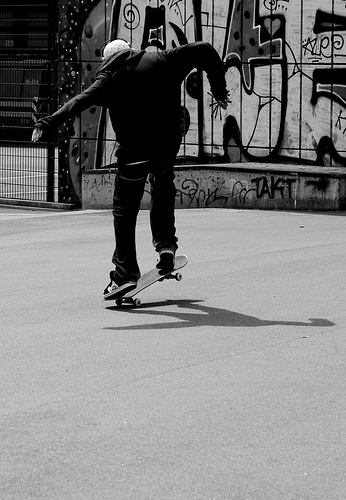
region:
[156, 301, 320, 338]
a shadow on the ground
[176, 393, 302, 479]
the ground is grey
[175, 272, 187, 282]
a wheel on the skateboard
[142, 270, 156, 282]
the skateboard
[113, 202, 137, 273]
person is wearing black pants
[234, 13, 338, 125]
tagging on the wall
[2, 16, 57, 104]
a fence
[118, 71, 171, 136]
a black sweater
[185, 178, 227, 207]
tagging on the wall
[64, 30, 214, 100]
the man is wearing headphones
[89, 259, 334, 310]
the man is on a skateboard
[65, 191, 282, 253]
the man is wearing dark jeans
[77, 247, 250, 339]
the man is wearing tennis shoes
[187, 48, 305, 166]
grafitti is on the wall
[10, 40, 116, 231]
a fence is by the wall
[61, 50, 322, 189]
the man is wearing a hoodie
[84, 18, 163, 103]
the man is wearing a hat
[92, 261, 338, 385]
the man's shadow is on the ground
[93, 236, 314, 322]
the skateboard is slanted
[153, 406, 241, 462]
the ground is grey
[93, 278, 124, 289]
the person is wearing shoes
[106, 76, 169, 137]
a black sweater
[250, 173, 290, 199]
tagging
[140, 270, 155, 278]
a skateboard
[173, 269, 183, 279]
wheel of the skateboard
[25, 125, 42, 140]
the persons hand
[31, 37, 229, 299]
the boy on the skateboard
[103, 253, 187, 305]
the skateboard under the boy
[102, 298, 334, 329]
the shadow on the ground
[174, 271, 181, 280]
the wheel on the skateboard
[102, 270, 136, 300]
the shoe on the boy's foot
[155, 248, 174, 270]
the button on the man's jacket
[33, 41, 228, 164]
the hoodie on the boy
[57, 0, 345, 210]
the graffitti on the walls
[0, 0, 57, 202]
the gate near the graffiti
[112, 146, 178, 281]
the long pants on the boy